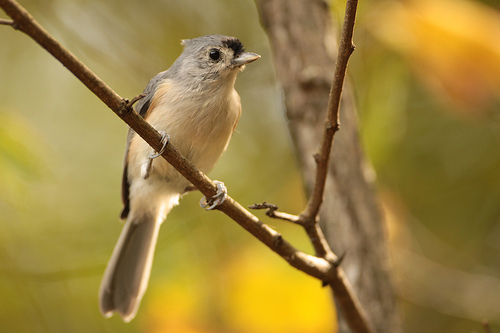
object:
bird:
[94, 31, 265, 322]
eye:
[208, 47, 222, 61]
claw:
[199, 180, 228, 211]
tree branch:
[0, 0, 371, 332]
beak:
[230, 51, 262, 65]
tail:
[97, 207, 173, 322]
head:
[174, 29, 263, 90]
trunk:
[249, 2, 397, 330]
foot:
[148, 130, 171, 159]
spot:
[230, 39, 243, 55]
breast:
[150, 94, 235, 169]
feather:
[133, 182, 175, 214]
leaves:
[382, 120, 489, 205]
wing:
[122, 76, 176, 219]